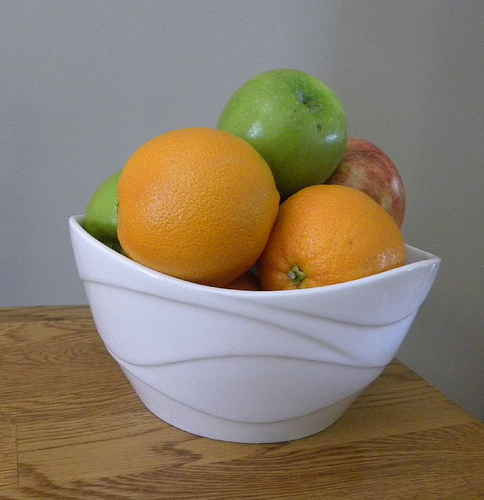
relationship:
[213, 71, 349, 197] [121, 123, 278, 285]
apple and orange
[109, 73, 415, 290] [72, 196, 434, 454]
fruit in bowl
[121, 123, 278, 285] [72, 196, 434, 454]
orange in bowl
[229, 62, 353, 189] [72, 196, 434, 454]
apple in bowl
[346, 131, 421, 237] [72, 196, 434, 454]
apple in bowl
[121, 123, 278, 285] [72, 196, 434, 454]
orange sits on bowl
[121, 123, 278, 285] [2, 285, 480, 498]
orange sitting on table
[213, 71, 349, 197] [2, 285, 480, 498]
apple sitting on table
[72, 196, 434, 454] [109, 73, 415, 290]
bowl of fruit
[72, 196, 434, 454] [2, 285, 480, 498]
bowl sitting on table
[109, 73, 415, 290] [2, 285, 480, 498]
fruit sitting on table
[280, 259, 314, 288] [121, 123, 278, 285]
stem of orange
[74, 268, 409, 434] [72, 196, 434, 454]
design on bowl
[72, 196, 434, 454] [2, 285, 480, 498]
bowl on table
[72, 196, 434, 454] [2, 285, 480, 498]
bowl of fruit on table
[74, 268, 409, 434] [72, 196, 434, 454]
design across bowl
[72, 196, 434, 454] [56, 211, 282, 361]
bowl has curved edge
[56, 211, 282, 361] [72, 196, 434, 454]
curved edge of bowl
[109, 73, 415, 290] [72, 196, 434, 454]
oranges and aples in container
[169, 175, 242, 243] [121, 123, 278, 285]
texture of orange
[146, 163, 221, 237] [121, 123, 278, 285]
peel of orange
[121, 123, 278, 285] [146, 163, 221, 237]
orange has peel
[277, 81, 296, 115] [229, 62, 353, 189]
specks across apple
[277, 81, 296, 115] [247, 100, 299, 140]
specks across skin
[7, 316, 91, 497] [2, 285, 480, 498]
grain of table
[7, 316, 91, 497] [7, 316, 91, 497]
grain of grain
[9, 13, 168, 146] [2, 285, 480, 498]
wall behind table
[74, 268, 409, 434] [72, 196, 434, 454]
pattern of bowl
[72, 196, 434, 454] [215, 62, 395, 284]
bowl of mixed fruit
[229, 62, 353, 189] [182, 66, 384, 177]
apple on top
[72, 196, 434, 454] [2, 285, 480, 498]
fruit bowl on table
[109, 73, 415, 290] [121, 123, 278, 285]
pieces of orange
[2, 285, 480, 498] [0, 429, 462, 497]
corner of table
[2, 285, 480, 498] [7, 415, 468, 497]
top of table